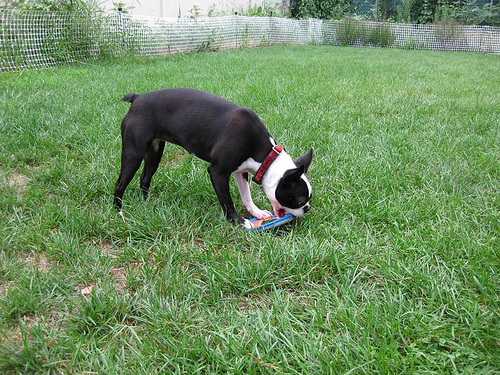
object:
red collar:
[248, 143, 283, 185]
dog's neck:
[254, 135, 294, 192]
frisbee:
[242, 211, 296, 234]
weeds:
[333, 15, 396, 47]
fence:
[1, 15, 500, 77]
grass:
[0, 45, 499, 375]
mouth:
[273, 206, 302, 222]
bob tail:
[119, 90, 139, 102]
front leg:
[232, 169, 257, 212]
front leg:
[206, 167, 238, 220]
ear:
[282, 164, 305, 186]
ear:
[292, 144, 314, 173]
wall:
[288, 0, 500, 27]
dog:
[110, 86, 312, 231]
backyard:
[0, 42, 499, 374]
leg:
[112, 155, 141, 212]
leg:
[137, 138, 165, 200]